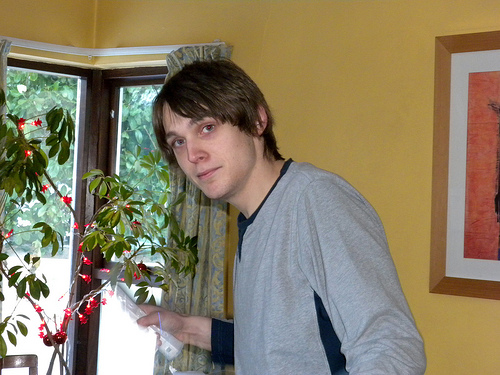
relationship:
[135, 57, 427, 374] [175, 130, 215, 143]
man has eyes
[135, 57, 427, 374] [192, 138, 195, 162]
man has nose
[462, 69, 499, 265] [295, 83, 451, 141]
painting hanging on wall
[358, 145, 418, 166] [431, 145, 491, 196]
wall has artwork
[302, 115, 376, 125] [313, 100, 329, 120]
walls has paint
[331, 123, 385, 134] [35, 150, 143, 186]
walls has windows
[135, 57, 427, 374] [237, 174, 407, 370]
man in a shirt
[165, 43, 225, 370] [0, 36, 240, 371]
curtains surround a window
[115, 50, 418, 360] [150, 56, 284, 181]
man has hair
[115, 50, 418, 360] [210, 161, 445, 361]
man wearing shirt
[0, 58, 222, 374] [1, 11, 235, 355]
window in background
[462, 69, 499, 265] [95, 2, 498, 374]
painting on wall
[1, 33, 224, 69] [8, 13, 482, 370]
curtain rod on wall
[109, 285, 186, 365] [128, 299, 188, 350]
controller in hand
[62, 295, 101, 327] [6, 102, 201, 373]
berries on plant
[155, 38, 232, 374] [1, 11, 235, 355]
curtain in background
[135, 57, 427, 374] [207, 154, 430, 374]
man wearing shirt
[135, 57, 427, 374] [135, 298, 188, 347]
man has hand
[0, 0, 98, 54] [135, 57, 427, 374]
wall behind man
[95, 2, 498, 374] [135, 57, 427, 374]
wall behind man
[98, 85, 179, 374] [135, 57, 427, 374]
window near man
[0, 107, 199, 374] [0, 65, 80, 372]
plant near window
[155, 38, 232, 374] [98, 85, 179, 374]
curtain by window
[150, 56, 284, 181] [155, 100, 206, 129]
hair on forehead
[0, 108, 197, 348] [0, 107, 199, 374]
leaves on plant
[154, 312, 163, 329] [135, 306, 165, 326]
stripe around thumb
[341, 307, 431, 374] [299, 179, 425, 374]
wrinkles on sleeve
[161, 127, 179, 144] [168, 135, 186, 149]
eyebrow above eye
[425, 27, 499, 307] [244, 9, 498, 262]
artwork hanging on wall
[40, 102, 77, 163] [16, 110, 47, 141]
leaves are on branch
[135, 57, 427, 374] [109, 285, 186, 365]
man holding controller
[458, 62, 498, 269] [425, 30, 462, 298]
painting in frame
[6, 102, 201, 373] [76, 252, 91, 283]
plant has flowers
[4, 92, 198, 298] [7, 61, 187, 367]
tree branches outside window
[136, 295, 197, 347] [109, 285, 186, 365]
hand holding controller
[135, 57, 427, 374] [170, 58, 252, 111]
man has hair